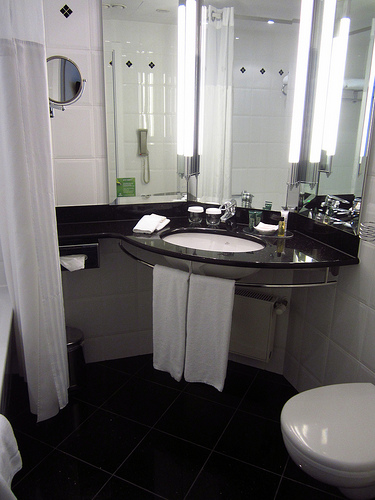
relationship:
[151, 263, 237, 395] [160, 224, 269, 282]
towels under sink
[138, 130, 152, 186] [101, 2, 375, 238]
phone reflected in mirror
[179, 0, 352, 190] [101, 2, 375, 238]
lights near mirror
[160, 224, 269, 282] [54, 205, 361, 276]
sink inside black counter-top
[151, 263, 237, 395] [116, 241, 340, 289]
towels hanging on bar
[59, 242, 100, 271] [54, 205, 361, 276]
dispenser under counter-top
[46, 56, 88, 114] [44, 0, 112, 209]
mirror on wall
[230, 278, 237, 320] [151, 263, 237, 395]
edge of towels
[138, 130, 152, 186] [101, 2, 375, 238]
phone inside mirror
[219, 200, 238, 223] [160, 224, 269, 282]
faucet above sink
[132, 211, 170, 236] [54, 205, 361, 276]
wash cloth on top of counter-top